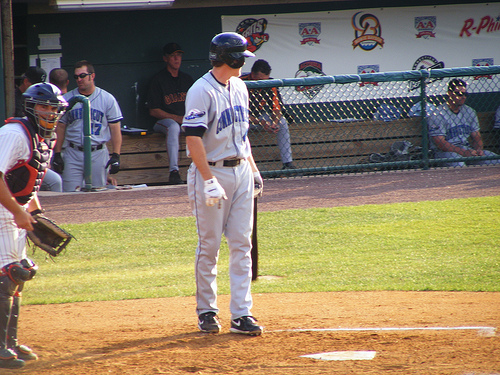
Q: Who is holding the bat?
A: The batter.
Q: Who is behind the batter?
A: The catcher.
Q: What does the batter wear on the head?
A: Helmet.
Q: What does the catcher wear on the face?
A: Face guard.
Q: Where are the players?
A: On the field.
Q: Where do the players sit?
A: In the dugout.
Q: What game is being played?
A: Baseball.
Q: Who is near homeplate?
A: The batter.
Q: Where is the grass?
A: On the field.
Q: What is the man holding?
A: A bat.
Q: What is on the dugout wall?
A: Logos.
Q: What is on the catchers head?
A: A helmet and mask.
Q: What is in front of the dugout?
A: A fence.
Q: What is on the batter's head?
A: A helmet.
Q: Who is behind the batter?
A: The catcher.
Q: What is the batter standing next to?
A: Home plate.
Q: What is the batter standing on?
A: Dirt.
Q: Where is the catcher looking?
A: Forward.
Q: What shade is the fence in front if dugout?
A: Green.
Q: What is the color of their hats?
A: Blue.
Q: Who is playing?
A: The baseball players.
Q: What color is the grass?
A: Green.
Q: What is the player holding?
A: His bat.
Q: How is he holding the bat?
A: With his left hand.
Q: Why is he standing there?
A: He is about to bat.